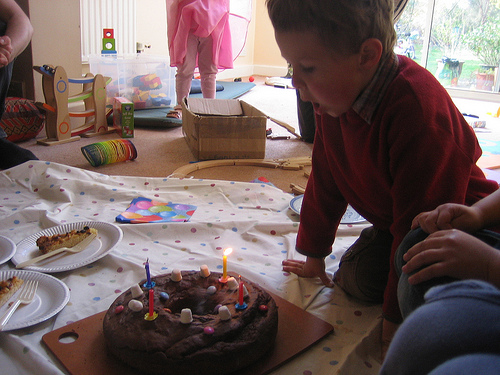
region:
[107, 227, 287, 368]
the cake with candles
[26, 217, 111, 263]
a piece of pie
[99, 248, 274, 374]
Round cake with candles and candy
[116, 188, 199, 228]
Paper napkins with balloons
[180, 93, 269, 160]
Brown cardboard box on floor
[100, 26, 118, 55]
Red and green blocks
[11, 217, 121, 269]
Cake on a white plate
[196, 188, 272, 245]
Red, blue, yellow and green polka dots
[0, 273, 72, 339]
White fork on white plate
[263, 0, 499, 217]
Boy with maroon shirt kneeling over cake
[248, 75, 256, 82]
Red ball on the floor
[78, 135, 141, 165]
Rainbow colored toy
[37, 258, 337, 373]
cake on a wooden platter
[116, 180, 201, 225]
birthday napkin on a floor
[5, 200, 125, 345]
paper plates on a floor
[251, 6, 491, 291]
little boy blowing out candles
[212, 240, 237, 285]
lit candle on a cake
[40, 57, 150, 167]
toys on the floor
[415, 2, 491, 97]
sliding glass doors in a home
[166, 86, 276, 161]
box on the floor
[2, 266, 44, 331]
plastic fork on plate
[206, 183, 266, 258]
tablecloth on a floor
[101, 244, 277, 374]
a chocolate cake with four candles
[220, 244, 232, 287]
a yellow birthday candle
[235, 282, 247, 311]
a red candle with a blue holder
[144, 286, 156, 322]
a red candle with a yellow holder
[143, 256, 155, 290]
a blue candle with a blue holder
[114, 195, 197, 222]
a napkin with many colorful balloons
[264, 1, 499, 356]
a young boy wearing a red sweater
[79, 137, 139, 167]
a rainbow colored slinky toy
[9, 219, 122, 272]
a white paper plate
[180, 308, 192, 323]
a fluffy white marshmallow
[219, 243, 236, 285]
yellow birthday candle with a yellow flame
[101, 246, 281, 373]
circular cake with candles on top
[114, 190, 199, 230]
colorful birthday napkin with balloons on it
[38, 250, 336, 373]
circular cake on a rectangular cutting board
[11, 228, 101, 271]
off white plastic fork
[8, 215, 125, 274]
paper plate with pizza and a fork on it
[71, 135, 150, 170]
rainbow colored slinky laying on its side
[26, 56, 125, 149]
colorful children's toy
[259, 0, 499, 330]
little boy wearing a red sweater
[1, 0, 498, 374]
little boy blowing out birthday candles